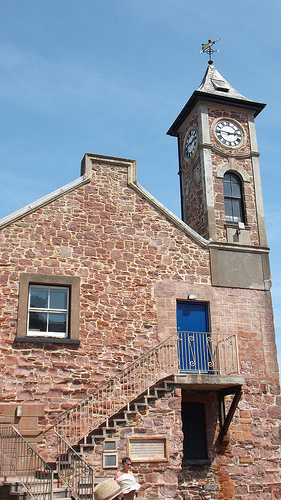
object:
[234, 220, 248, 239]
camera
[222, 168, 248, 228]
window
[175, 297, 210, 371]
door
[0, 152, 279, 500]
wall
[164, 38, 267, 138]
roof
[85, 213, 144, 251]
stone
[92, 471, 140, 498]
hats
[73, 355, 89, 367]
stone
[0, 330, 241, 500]
railing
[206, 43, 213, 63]
rod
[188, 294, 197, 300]
lamp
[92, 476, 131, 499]
hat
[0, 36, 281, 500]
building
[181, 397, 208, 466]
door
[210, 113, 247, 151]
clock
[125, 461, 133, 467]
sunglasses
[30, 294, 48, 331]
tree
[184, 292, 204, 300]
light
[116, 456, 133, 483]
woman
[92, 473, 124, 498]
tan hat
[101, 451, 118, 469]
chalkboard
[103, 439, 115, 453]
chalkboard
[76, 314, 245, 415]
rail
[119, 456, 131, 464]
hair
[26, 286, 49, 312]
reflection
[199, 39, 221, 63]
cross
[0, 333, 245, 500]
staircase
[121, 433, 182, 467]
plaque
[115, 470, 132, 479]
shirt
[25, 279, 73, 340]
window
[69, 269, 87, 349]
framing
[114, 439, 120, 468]
framing